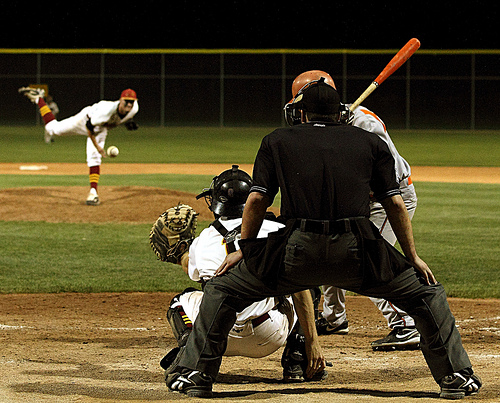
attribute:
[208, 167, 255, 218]
helmet — black, backwards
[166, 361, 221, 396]
shoe — black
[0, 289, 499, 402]
dirt — brown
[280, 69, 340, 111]
helmet — red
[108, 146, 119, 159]
baseball — flying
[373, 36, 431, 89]
top — red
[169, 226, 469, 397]
legs — spread